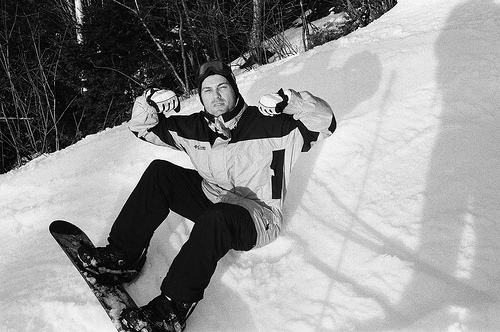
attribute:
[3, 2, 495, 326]
snow — white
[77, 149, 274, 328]
pants — black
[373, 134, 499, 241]
snow — WHITE